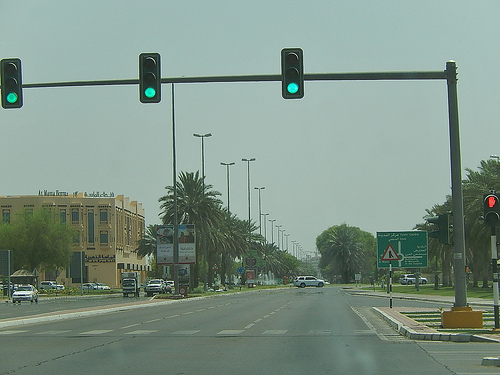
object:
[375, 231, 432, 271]
sign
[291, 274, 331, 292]
suv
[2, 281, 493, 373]
street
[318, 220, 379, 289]
trees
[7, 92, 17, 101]
light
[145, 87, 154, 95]
light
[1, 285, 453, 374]
road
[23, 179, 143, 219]
roof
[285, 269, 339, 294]
truck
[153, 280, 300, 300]
divider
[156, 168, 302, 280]
palm trees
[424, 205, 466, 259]
traffic light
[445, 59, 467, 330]
pole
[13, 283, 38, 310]
car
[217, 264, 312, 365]
road merges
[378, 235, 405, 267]
sign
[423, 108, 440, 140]
ground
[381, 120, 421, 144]
ground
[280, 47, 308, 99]
traffic light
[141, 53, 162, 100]
traffic light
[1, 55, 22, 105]
traffic light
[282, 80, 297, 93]
green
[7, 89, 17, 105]
green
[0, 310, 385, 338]
crosswalk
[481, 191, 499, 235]
traffic light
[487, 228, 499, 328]
pole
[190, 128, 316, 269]
lights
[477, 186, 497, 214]
sign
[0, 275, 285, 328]
median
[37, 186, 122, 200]
name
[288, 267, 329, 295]
car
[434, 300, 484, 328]
base